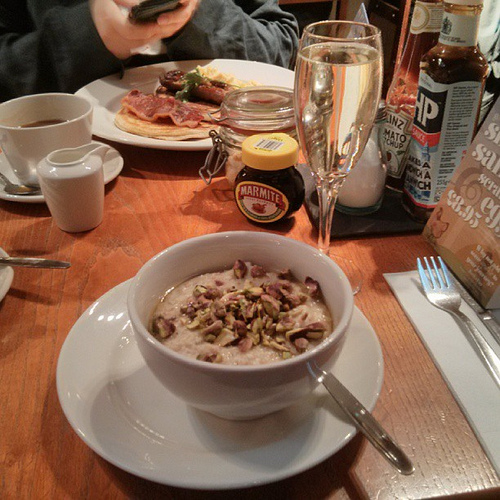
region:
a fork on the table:
[413, 252, 498, 420]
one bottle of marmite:
[231, 128, 308, 230]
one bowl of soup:
[124, 223, 357, 427]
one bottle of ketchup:
[381, 1, 441, 196]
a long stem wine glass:
[291, 12, 386, 252]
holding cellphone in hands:
[84, 1, 204, 61]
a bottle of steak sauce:
[405, 0, 491, 217]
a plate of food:
[71, 51, 291, 153]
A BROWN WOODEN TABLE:
[2, 48, 497, 498]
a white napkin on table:
[381, 252, 498, 480]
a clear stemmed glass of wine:
[295, 14, 380, 254]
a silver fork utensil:
[409, 245, 496, 402]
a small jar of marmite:
[226, 133, 308, 228]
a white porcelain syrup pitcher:
[32, 136, 107, 233]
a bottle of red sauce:
[389, 2, 486, 218]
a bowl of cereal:
[132, 236, 353, 413]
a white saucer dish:
[51, 266, 388, 488]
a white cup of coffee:
[1, 86, 128, 206]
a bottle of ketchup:
[369, 4, 446, 188]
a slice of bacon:
[122, 85, 222, 136]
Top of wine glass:
[295, 17, 383, 45]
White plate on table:
[83, 340, 138, 436]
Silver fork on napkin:
[416, 246, 465, 339]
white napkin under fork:
[396, 266, 417, 311]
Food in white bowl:
[151, 284, 261, 330]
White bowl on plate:
[175, 370, 240, 399]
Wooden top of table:
[134, 195, 176, 233]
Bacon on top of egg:
[112, 83, 207, 125]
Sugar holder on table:
[33, 138, 120, 235]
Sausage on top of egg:
[158, 62, 227, 98]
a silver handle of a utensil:
[310, 363, 414, 478]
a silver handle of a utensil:
[454, 307, 499, 402]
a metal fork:
[416, 251, 498, 398]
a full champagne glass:
[295, 20, 385, 257]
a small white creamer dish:
[38, 141, 111, 230]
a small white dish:
[51, 271, 384, 486]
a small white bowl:
[131, 229, 347, 414]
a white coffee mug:
[1, 93, 94, 189]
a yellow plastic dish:
[241, 133, 294, 165]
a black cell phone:
[127, 1, 181, 25]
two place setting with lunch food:
[75, 19, 417, 419]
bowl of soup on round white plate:
[126, 219, 373, 387]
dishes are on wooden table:
[46, 206, 180, 310]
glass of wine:
[293, 9, 390, 274]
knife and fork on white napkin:
[409, 240, 494, 404]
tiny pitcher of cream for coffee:
[35, 140, 117, 233]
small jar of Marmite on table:
[219, 122, 308, 224]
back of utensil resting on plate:
[311, 374, 421, 480]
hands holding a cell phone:
[76, 0, 211, 53]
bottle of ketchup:
[367, 6, 437, 205]